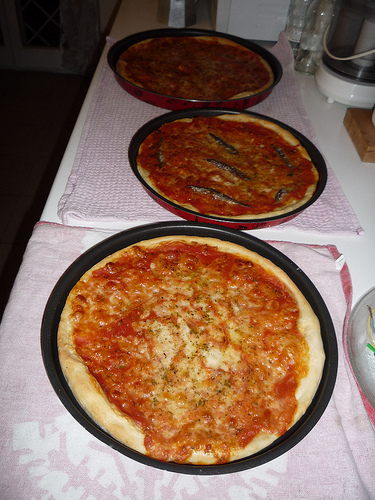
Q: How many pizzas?
A: Three.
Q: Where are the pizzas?
A: On a table.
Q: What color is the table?
A: Pink and white.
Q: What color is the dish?
A: Black.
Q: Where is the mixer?
A: Right corner.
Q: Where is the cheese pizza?
A: First one on the bottom.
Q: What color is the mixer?
A: White.